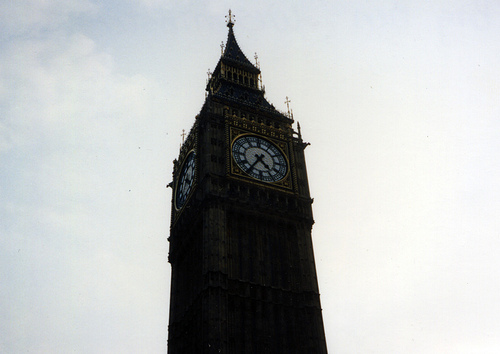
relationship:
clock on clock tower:
[232, 135, 288, 183] [165, 7, 327, 352]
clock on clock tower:
[173, 149, 198, 212] [165, 7, 327, 352]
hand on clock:
[254, 154, 269, 168] [226, 130, 293, 196]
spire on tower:
[208, 5, 266, 87] [165, 11, 335, 347]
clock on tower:
[230, 128, 292, 187] [145, 7, 355, 352]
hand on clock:
[246, 154, 271, 174] [230, 132, 302, 187]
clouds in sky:
[48, 44, 113, 146] [3, 3, 492, 352]